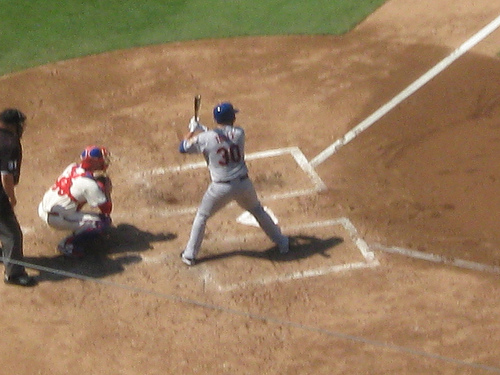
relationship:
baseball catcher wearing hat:
[36, 145, 114, 260] [72, 139, 105, 162]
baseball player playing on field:
[179, 93, 290, 265] [1, 2, 498, 374]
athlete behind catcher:
[0, 106, 40, 286] [36, 144, 130, 264]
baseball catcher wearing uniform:
[36, 145, 114, 260] [34, 161, 108, 236]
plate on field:
[234, 201, 280, 231] [1, 0, 499, 374]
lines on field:
[117, 19, 498, 295] [1, 0, 499, 374]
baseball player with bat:
[179, 93, 290, 265] [192, 93, 200, 119]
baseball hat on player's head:
[211, 101, 241, 120] [197, 102, 242, 127]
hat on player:
[202, 103, 276, 140] [167, 110, 331, 281]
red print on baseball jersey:
[211, 125, 243, 173] [184, 120, 252, 189]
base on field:
[233, 198, 282, 237] [1, 2, 498, 374]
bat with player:
[174, 95, 215, 132] [137, 84, 322, 271]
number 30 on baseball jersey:
[217, 146, 241, 166] [182, 123, 248, 182]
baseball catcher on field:
[38, 145, 118, 260] [1, 2, 498, 374]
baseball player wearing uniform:
[179, 93, 290, 265] [176, 129, 281, 257]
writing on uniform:
[216, 132, 236, 144] [188, 128, 278, 250]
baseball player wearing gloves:
[179, 93, 290, 265] [185, 114, 204, 136]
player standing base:
[176, 126, 294, 266] [235, 202, 280, 226]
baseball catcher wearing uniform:
[36, 145, 114, 260] [31, 123, 115, 261]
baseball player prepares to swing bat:
[175, 91, 294, 267] [190, 91, 203, 126]